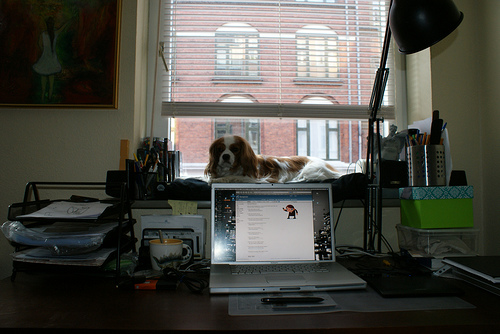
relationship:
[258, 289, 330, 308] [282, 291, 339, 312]
pen on top of paper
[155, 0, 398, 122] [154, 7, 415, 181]
blinds for window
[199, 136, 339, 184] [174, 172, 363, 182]
dog on seal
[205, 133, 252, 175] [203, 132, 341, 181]
head of dog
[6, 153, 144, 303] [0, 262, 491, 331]
organizer on desk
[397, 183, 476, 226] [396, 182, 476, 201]
box with lid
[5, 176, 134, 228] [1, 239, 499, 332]
tray on desk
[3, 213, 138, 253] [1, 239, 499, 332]
tray on desk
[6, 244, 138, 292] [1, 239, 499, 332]
tray on desk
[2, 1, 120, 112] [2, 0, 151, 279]
picture on wall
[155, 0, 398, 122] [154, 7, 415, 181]
blinds on window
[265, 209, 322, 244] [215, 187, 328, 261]
character on screen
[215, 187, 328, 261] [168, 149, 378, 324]
screen of laptop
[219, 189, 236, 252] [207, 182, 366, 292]
icons on laptop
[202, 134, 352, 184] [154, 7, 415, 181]
dog near window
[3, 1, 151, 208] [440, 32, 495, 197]
wall in room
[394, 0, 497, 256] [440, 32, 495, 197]
wall in room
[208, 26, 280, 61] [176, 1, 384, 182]
window of nearby building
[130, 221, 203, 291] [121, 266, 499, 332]
cup on desk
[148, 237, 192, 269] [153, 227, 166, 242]
cup holding pen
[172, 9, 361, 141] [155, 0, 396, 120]
building outside of blinds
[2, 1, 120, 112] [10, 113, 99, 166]
picture on wall